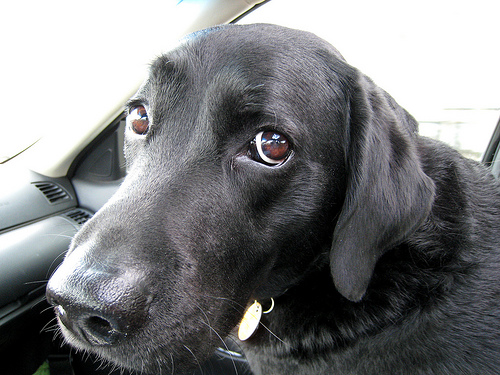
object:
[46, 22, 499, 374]
dog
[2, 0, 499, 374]
car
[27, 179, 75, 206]
ac duct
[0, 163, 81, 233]
dashboard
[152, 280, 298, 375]
cheek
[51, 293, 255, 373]
mouth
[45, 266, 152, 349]
nose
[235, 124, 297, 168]
eye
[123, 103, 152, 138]
eye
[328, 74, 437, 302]
ear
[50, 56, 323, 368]
face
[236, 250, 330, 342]
collar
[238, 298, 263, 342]
tag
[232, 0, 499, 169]
window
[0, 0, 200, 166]
windshield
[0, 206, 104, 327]
glovebox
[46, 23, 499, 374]
fur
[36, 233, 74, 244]
whiskers